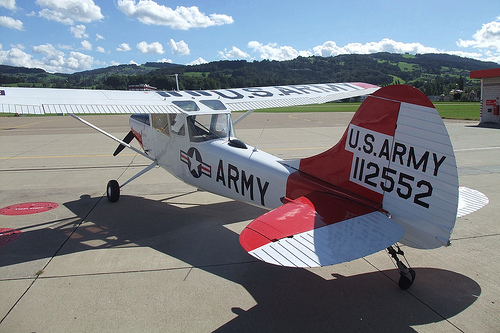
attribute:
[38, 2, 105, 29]
clouds — whilte, fluffy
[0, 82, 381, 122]
wing — large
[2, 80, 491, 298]
plane — white, red, whilte, blue, army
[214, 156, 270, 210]
letters — black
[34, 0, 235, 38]
clouds — white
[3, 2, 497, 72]
sky — blue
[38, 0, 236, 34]
cloud — puffy, white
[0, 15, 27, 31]
cloud — white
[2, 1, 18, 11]
cloud — white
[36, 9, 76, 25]
cloud — white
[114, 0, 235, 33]
cloud — white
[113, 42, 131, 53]
cloud — white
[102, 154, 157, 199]
landing gear — main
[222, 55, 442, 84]
moutains — green topped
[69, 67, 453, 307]
plane — small 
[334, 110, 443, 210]
lettering — black 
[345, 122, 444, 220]
writing — Army, plane number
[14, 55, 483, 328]
plane — Window , Wing 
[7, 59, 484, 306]
plane — Window , white 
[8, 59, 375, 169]
wing — white, Red 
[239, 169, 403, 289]
wing — Red , white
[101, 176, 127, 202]
tire — plane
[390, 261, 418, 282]
tire — Black 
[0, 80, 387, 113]
wings — Large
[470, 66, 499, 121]
building — concrete, block, red, white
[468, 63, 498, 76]
roof — red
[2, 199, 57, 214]
manhole cover — red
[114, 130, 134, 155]
propeller blade — black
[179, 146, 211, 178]
logo — army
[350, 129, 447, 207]
letters — ID#, black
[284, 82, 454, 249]
tail — Red , white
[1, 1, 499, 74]
clouds — white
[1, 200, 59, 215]
circle — Round, red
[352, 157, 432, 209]
112552 — Black, number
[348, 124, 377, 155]
letters — Black, U.S.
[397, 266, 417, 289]
wheel — black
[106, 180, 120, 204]
wheel — black, largest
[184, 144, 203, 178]
circle — Dark, navy, blue, round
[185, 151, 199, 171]
star — white 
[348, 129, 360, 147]
letter — black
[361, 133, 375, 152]
letter — black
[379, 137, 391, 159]
letter — black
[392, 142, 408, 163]
letter — black